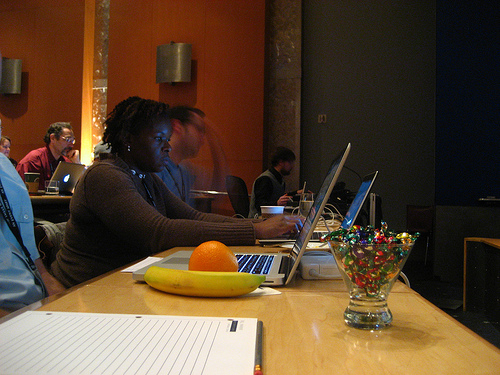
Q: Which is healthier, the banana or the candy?
A: The banana is healthier than the candy.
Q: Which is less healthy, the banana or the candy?
A: The candy is less healthy than the banana.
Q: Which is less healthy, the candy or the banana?
A: The candy is less healthy than the banana.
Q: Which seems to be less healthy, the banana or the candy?
A: The candy is less healthy than the banana.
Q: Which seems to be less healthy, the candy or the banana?
A: The candy is less healthy than the banana.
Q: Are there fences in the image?
A: No, there are no fences.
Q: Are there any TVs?
A: No, there are no tvs.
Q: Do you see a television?
A: No, there are no televisions.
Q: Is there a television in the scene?
A: No, there are no televisions.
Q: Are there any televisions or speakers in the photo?
A: No, there are no televisions or speakers.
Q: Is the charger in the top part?
A: No, the charger is in the bottom of the image.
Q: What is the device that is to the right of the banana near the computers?
A: The device is a charger.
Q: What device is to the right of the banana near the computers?
A: The device is a charger.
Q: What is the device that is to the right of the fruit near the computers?
A: The device is a charger.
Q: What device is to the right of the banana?
A: The device is a charger.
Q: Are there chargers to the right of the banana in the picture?
A: Yes, there is a charger to the right of the banana.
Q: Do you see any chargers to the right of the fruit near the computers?
A: Yes, there is a charger to the right of the banana.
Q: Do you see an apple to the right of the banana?
A: No, there is a charger to the right of the banana.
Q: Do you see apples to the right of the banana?
A: No, there is a charger to the right of the banana.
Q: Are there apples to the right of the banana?
A: No, there is a charger to the right of the banana.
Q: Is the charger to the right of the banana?
A: Yes, the charger is to the right of the banana.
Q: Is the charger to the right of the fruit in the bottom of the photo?
A: Yes, the charger is to the right of the banana.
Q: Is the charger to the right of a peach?
A: No, the charger is to the right of the banana.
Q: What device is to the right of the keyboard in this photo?
A: The device is a charger.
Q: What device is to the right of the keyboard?
A: The device is a charger.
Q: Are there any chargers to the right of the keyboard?
A: Yes, there is a charger to the right of the keyboard.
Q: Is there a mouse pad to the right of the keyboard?
A: No, there is a charger to the right of the keyboard.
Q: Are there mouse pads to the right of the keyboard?
A: No, there is a charger to the right of the keyboard.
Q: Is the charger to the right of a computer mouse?
A: No, the charger is to the right of the keyboard.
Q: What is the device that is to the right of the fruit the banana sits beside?
A: The device is a charger.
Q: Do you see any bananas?
A: Yes, there is a banana.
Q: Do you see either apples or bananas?
A: Yes, there is a banana.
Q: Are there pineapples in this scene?
A: No, there are no pineapples.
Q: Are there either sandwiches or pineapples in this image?
A: No, there are no pineapples or sandwiches.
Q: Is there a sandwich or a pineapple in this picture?
A: No, there are no pineapples or sandwiches.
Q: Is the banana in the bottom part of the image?
A: Yes, the banana is in the bottom of the image.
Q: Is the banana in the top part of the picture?
A: No, the banana is in the bottom of the image.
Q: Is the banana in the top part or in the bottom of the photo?
A: The banana is in the bottom of the image.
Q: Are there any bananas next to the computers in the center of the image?
A: Yes, there is a banana next to the computers.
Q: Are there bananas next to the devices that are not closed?
A: Yes, there is a banana next to the computers.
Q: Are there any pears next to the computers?
A: No, there is a banana next to the computers.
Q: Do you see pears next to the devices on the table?
A: No, there is a banana next to the computers.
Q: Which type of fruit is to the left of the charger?
A: The fruit is a banana.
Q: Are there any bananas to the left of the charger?
A: Yes, there is a banana to the left of the charger.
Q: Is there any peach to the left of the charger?
A: No, there is a banana to the left of the charger.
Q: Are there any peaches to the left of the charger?
A: No, there is a banana to the left of the charger.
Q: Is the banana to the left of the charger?
A: Yes, the banana is to the left of the charger.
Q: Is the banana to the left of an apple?
A: No, the banana is to the left of the charger.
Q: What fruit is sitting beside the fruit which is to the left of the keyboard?
A: The fruit is a banana.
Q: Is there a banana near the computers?
A: Yes, there is a banana near the computers.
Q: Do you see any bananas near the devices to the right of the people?
A: Yes, there is a banana near the computers.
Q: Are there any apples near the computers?
A: No, there is a banana near the computers.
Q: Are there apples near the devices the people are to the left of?
A: No, there is a banana near the computers.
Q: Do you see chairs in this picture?
A: Yes, there is a chair.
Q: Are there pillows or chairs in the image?
A: Yes, there is a chair.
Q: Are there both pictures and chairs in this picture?
A: No, there is a chair but no pictures.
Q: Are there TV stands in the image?
A: No, there are no TV stands.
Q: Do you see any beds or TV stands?
A: No, there are no TV stands or beds.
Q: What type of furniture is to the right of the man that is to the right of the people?
A: The piece of furniture is a chair.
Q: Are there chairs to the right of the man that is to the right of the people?
A: Yes, there is a chair to the right of the man.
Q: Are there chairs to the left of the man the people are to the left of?
A: No, the chair is to the right of the man.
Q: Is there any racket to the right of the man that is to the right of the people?
A: No, there is a chair to the right of the man.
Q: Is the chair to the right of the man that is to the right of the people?
A: Yes, the chair is to the right of the man.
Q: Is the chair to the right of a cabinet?
A: No, the chair is to the right of the man.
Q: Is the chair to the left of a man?
A: No, the chair is to the right of a man.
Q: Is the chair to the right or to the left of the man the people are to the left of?
A: The chair is to the right of the man.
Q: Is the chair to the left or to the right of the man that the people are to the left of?
A: The chair is to the right of the man.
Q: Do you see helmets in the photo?
A: No, there are no helmets.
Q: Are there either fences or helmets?
A: No, there are no helmets or fences.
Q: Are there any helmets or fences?
A: No, there are no helmets or fences.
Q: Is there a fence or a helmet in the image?
A: No, there are no helmets or fences.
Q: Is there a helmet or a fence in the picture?
A: No, there are no helmets or fences.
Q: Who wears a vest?
A: The man wears a vest.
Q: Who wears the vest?
A: The man wears a vest.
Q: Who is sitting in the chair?
A: The man is sitting in the chair.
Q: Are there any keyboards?
A: Yes, there is a keyboard.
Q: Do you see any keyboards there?
A: Yes, there is a keyboard.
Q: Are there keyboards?
A: Yes, there is a keyboard.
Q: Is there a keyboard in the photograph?
A: Yes, there is a keyboard.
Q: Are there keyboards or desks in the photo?
A: Yes, there is a keyboard.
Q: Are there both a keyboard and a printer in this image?
A: No, there is a keyboard but no printers.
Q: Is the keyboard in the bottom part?
A: Yes, the keyboard is in the bottom of the image.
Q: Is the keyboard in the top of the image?
A: No, the keyboard is in the bottom of the image.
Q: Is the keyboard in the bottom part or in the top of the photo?
A: The keyboard is in the bottom of the image.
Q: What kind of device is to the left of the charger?
A: The device is a keyboard.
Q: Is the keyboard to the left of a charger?
A: Yes, the keyboard is to the left of a charger.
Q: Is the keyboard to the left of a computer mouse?
A: No, the keyboard is to the left of a charger.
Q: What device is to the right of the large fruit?
A: The device is a keyboard.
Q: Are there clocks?
A: No, there are no clocks.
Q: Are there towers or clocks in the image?
A: No, there are no clocks or towers.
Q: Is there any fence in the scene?
A: No, there are no fences.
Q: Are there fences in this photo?
A: No, there are no fences.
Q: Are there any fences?
A: No, there are no fences.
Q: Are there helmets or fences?
A: No, there are no fences or helmets.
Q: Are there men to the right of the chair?
A: No, the man is to the left of the chair.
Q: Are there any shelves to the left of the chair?
A: No, there is a man to the left of the chair.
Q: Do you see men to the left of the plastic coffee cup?
A: Yes, there is a man to the left of the coffee cup.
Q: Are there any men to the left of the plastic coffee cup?
A: Yes, there is a man to the left of the coffee cup.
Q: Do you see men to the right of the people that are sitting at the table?
A: Yes, there is a man to the right of the people.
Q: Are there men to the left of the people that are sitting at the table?
A: No, the man is to the right of the people.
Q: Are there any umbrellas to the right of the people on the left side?
A: No, there is a man to the right of the people.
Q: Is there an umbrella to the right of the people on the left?
A: No, there is a man to the right of the people.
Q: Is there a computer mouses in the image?
A: No, there are no computer mousess.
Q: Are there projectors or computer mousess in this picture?
A: No, there are no computer mousess or projectors.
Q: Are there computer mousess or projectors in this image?
A: No, there are no computer mousess or projectors.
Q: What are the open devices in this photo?
A: The devices are computers.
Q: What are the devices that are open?
A: The devices are computers.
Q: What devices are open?
A: The devices are computers.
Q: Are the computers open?
A: Yes, the computers are open.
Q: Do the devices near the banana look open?
A: Yes, the computers are open.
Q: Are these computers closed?
A: No, the computers are open.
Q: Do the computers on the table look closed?
A: No, the computers are open.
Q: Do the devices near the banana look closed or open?
A: The computers are open.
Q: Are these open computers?
A: Yes, these are open computers.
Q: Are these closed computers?
A: No, these are open computers.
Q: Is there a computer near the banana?
A: Yes, there are computers near the banana.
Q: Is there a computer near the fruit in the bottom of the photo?
A: Yes, there are computers near the banana.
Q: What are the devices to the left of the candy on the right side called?
A: The devices are computers.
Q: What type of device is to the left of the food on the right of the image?
A: The devices are computers.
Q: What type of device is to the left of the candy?
A: The devices are computers.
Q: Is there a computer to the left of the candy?
A: Yes, there are computers to the left of the candy.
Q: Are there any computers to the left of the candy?
A: Yes, there are computers to the left of the candy.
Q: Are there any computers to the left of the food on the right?
A: Yes, there are computers to the left of the candy.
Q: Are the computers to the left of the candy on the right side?
A: Yes, the computers are to the left of the candy.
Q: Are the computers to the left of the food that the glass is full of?
A: Yes, the computers are to the left of the candy.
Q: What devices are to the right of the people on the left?
A: The devices are computers.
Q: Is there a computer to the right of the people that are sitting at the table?
A: Yes, there are computers to the right of the people.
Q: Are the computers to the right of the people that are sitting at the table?
A: Yes, the computers are to the right of the people.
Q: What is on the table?
A: The computers are on the table.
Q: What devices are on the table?
A: The devices are computers.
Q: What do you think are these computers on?
A: The computers are on the table.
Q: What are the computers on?
A: The computers are on the table.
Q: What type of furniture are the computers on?
A: The computers are on the table.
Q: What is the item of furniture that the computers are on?
A: The piece of furniture is a table.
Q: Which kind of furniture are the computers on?
A: The computers are on the table.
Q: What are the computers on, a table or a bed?
A: The computers are on a table.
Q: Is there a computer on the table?
A: Yes, there are computers on the table.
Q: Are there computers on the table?
A: Yes, there are computers on the table.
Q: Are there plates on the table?
A: No, there are computers on the table.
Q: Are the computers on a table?
A: Yes, the computers are on a table.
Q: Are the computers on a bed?
A: No, the computers are on a table.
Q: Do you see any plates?
A: No, there are no plates.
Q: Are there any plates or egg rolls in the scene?
A: No, there are no plates or egg rolls.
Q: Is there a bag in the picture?
A: No, there are no bags.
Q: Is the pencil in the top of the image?
A: No, the pencil is in the bottom of the image.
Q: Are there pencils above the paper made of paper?
A: Yes, there is a pencil above the paper.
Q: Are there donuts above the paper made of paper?
A: No, there is a pencil above the paper.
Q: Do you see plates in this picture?
A: No, there are no plates.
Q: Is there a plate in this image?
A: No, there are no plates.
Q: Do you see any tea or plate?
A: No, there are no plates or tea.